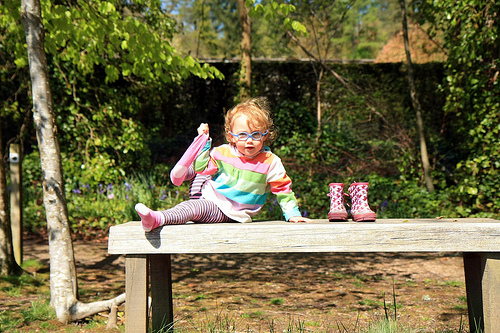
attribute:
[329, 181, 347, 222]
boot — pink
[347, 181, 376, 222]
boot — pink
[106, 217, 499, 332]
bench — brown, wooden, wood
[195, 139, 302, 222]
sweater — multi-colored, pink, blue, green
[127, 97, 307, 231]
child — girl, female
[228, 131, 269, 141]
glasses — blue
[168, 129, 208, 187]
sock — pink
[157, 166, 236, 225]
tights — pink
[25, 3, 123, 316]
trunk — white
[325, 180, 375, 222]
boots — red, pink, white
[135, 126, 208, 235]
socks — pink, white